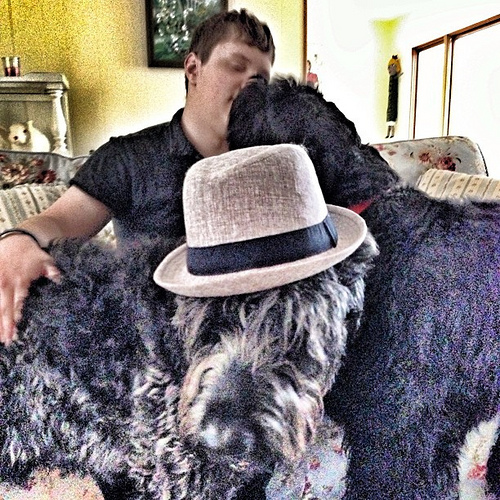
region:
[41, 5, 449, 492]
a guy with two dogs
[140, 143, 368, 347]
a dog wearing a hat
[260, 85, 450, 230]
a black dog with red collar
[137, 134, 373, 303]
a brown hat the dog is wearing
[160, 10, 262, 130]
a guy with dogs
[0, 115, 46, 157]
a bunny behind the guy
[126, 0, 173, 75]
a picture frame on the wall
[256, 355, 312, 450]
a hairy fur of the dog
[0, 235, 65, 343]
a hand of the man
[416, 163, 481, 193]
a pillow next to the man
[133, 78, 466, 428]
Two dogs and a man sitting.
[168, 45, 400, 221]
The dog is kissing the man.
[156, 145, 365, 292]
The dog has a hat on his head.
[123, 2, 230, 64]
A picture on the wall.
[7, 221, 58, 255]
The man has a black string on arm.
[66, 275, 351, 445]
The dog is white and black.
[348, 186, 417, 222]
The dog has a red collar.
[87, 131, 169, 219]
The man is wearing a black shirt.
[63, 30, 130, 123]
The wall is yellow.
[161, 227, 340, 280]
The hat has a black ribbon around it.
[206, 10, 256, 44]
Person has brown hair.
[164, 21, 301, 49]
Person has short hair.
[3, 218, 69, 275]
Black band around person's wrist.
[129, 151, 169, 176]
Person wearing black shirt.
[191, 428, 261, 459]
Dog has black nose.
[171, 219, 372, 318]
Gray dog wearing hat on head.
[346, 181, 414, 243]
Dog wearing red collar.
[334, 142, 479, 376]
Black dog behind gray dog.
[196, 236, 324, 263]
Black band around hat.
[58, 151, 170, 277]
Person sitting on printed couch.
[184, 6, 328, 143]
man kissing black dog with red collar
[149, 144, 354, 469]
grey and black dog with tan hat on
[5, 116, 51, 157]
white rabbit on shelf by wall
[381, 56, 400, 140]
old doll with a black dress hanging on wall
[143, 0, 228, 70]
floral picture hanging on wall behind man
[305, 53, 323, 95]
Michael Jackson poster hanging on back wall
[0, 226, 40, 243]
band on right hand of man with a black shirt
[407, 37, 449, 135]
sliding glass door with wood trim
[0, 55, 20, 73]
candle on top shelf by the wall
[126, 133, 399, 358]
Hat on a dog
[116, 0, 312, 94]
picture on yellow wall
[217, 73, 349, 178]
black dog kissing man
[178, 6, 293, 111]
man has short brown hair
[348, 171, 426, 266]
dog has red collar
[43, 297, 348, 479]
grey and white dog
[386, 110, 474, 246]
couch has floral pattern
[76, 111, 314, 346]
man wearing black shirt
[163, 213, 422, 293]
hat has black band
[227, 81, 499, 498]
A long haired black dog.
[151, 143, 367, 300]
Grey hat with black band.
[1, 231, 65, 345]
A mans right hand.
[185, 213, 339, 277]
Black ring around a grey hat.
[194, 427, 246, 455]
A dogs grey nose.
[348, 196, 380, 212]
Red collar on a black dog.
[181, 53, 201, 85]
A mans right ear.